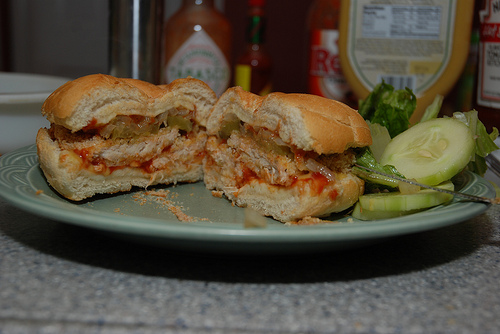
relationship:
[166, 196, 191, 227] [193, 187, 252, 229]
crumbs on plate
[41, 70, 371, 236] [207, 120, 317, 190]
sandwich has chicken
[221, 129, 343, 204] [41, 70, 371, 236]
sauce on sandwich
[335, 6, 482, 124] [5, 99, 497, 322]
mustard on table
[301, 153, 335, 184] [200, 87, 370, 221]
onion on sandwich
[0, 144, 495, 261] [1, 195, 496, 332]
plate on tabletop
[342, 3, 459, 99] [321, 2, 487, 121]
label on bottle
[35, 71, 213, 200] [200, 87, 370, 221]
sandwich next to sandwich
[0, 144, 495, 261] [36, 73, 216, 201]
plate under sandwich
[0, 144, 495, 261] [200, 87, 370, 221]
plate under sandwich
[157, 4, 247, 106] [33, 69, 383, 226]
bottle behind sandwich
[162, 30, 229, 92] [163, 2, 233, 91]
label on bottle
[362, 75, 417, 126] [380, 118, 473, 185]
green lettuce next to cucumber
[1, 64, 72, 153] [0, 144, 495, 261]
bowl behind plate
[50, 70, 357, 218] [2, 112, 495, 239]
food on plate